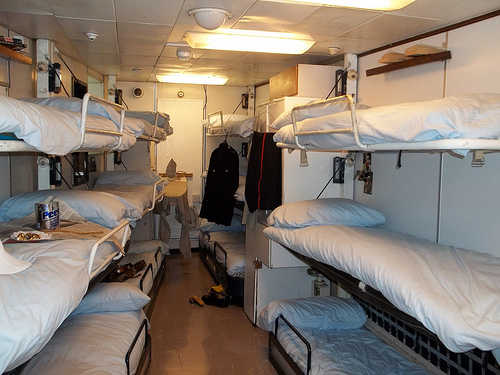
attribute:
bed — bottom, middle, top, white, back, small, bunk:
[308, 97, 428, 159]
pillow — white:
[43, 96, 92, 110]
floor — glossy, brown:
[172, 323, 233, 355]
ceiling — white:
[102, 0, 155, 28]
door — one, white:
[161, 100, 196, 159]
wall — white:
[443, 46, 482, 78]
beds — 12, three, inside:
[294, 101, 458, 282]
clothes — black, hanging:
[11, 44, 53, 89]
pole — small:
[339, 64, 363, 87]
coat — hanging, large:
[205, 152, 238, 197]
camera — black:
[36, 58, 71, 72]